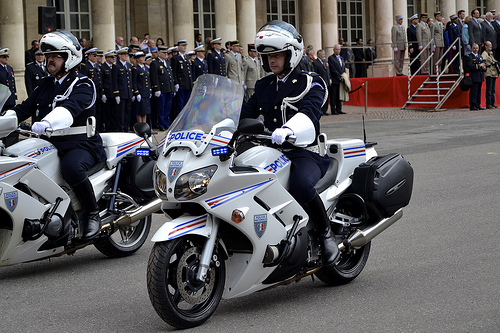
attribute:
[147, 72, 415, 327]
motorcycle — red,white, blue, white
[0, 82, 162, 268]
motorcycle — red,white, blue, white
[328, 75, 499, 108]
platform — red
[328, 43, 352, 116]
man — standing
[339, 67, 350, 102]
overcoat — beige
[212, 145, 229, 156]
light — blue, warning light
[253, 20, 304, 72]
helmet — white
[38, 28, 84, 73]
helmet — white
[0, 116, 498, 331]
street — grey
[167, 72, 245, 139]
windshield — clear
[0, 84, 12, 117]
windshield — clear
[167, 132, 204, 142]
word — blue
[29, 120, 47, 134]
glove — white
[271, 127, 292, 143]
glove — white